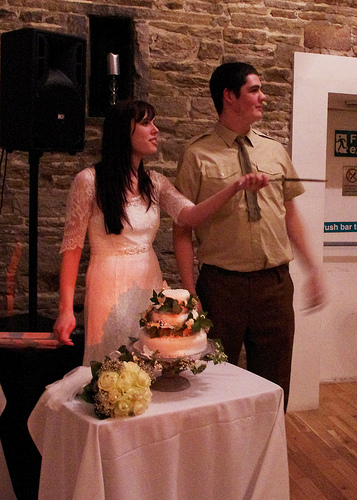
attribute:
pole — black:
[28, 150, 42, 323]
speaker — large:
[2, 22, 93, 163]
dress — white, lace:
[56, 161, 195, 366]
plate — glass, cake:
[140, 336, 250, 375]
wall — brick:
[151, 18, 207, 102]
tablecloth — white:
[73, 386, 323, 471]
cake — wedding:
[131, 283, 216, 394]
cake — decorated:
[113, 280, 223, 375]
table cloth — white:
[26, 364, 294, 498]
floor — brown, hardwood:
[279, 395, 341, 480]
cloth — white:
[26, 358, 290, 498]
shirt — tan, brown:
[173, 118, 304, 271]